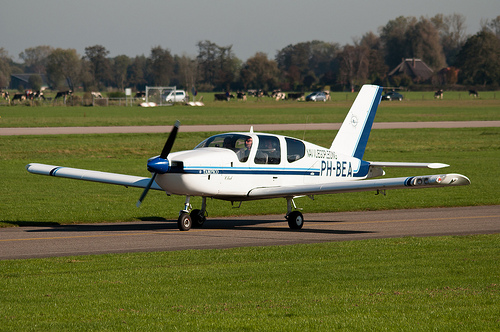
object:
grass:
[0, 230, 499, 331]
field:
[0, 88, 499, 330]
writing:
[306, 148, 337, 160]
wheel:
[285, 209, 305, 231]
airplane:
[24, 83, 470, 232]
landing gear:
[281, 194, 304, 230]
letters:
[323, 160, 333, 178]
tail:
[328, 83, 385, 158]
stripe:
[352, 85, 385, 158]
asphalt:
[0, 204, 499, 262]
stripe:
[0, 213, 499, 242]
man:
[236, 134, 254, 161]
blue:
[2, 0, 356, 35]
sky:
[0, 0, 499, 68]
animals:
[210, 93, 234, 103]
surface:
[0, 204, 499, 259]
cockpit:
[196, 131, 280, 167]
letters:
[333, 160, 341, 177]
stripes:
[179, 168, 323, 176]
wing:
[248, 172, 470, 204]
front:
[133, 122, 224, 206]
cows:
[51, 88, 72, 101]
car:
[163, 90, 187, 104]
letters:
[318, 159, 328, 177]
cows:
[430, 88, 446, 101]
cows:
[465, 89, 480, 100]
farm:
[0, 58, 499, 109]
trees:
[236, 50, 283, 101]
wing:
[25, 161, 164, 193]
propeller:
[136, 120, 181, 203]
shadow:
[0, 215, 380, 234]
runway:
[0, 204, 499, 258]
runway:
[0, 119, 499, 135]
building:
[382, 57, 432, 89]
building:
[6, 72, 51, 93]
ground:
[0, 91, 498, 332]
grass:
[0, 126, 498, 227]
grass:
[0, 90, 499, 129]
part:
[125, 116, 228, 226]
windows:
[253, 134, 282, 165]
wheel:
[175, 211, 195, 232]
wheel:
[187, 207, 207, 227]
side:
[175, 140, 376, 197]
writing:
[318, 158, 354, 178]